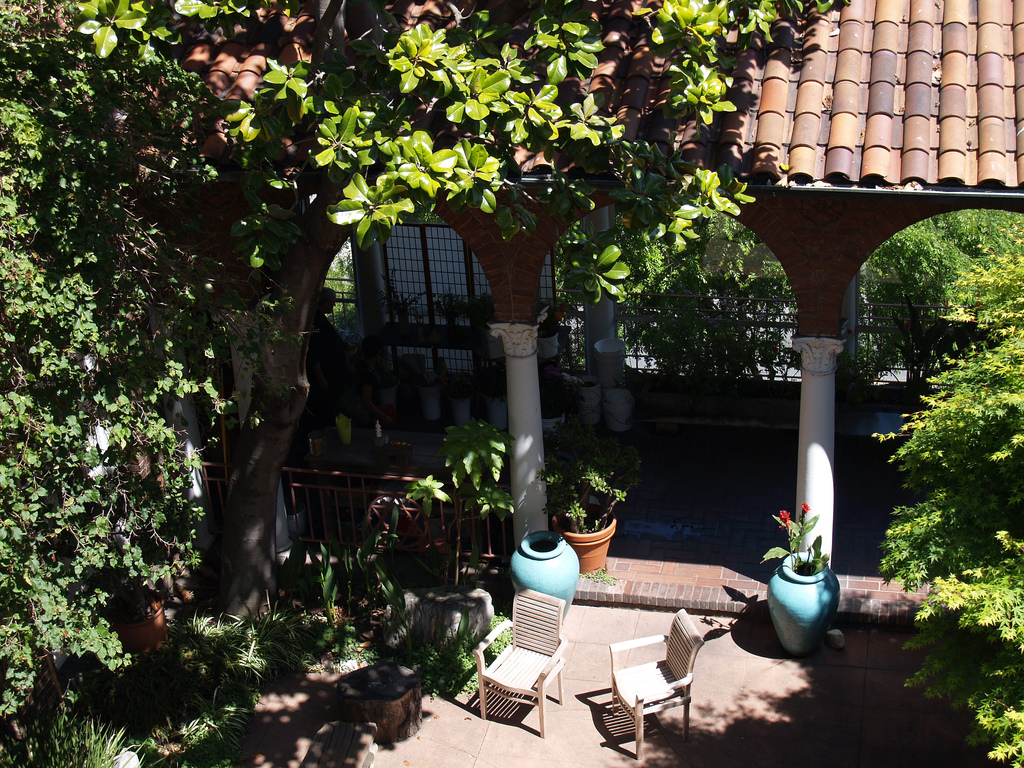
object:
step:
[614, 580, 662, 616]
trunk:
[214, 438, 282, 626]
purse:
[606, 405, 637, 432]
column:
[489, 310, 561, 576]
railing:
[170, 461, 519, 566]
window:
[355, 225, 558, 379]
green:
[433, 64, 524, 124]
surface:
[805, 84, 936, 158]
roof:
[639, 0, 1023, 202]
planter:
[761, 548, 845, 662]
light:
[588, 596, 737, 768]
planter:
[502, 528, 586, 627]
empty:
[519, 530, 567, 558]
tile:
[825, 78, 864, 117]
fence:
[559, 284, 954, 394]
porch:
[280, 393, 971, 585]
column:
[786, 332, 854, 588]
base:
[780, 641, 822, 661]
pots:
[483, 391, 512, 433]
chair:
[605, 606, 706, 765]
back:
[659, 608, 705, 688]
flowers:
[757, 499, 834, 585]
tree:
[79, 0, 828, 652]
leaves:
[396, 138, 431, 172]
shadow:
[421, 652, 565, 742]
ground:
[0, 452, 1023, 768]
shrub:
[541, 414, 649, 535]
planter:
[559, 518, 619, 580]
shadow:
[695, 579, 792, 663]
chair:
[469, 584, 573, 741]